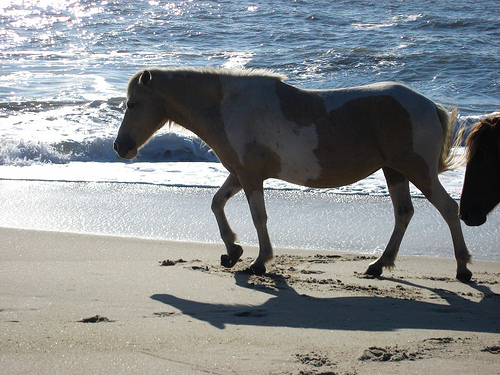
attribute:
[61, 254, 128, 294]
sand — brown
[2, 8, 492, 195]
water — calm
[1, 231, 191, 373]
sand — wet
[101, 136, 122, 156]
nose — black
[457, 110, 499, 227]
horse — second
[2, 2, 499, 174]
water — wavy, dark, ocean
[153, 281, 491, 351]
dirt — wet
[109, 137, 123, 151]
nose — black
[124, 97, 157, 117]
eye — large, black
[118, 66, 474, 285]
horse — walking, tan, white, brown and white, brown, beige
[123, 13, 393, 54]
water — choppy, rough 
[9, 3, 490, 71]
ocean — blue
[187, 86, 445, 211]
hair — golden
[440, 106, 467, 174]
tail — beige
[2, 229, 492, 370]
sand — brown, wet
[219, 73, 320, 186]
spot — white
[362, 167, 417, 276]
leg — back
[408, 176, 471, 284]
leg — back